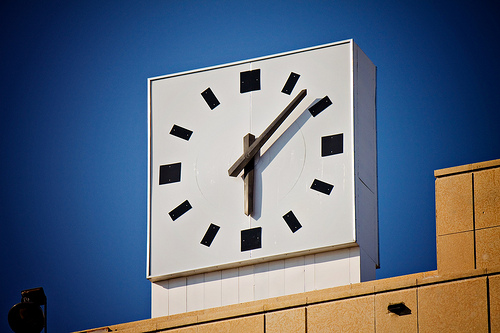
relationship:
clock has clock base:
[145, 42, 356, 277] [149, 248, 362, 317]